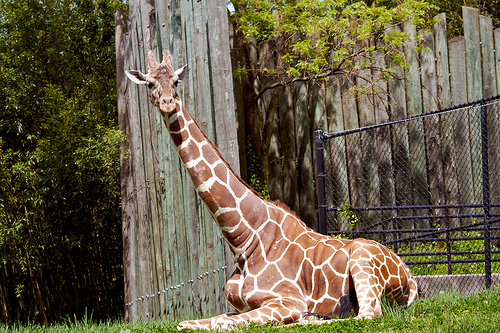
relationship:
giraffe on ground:
[120, 43, 433, 329] [4, 293, 499, 332]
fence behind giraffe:
[113, 4, 497, 317] [120, 43, 433, 329]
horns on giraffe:
[141, 49, 174, 68] [120, 43, 433, 329]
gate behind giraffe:
[305, 112, 499, 291] [120, 43, 433, 329]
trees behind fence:
[0, 1, 349, 286] [113, 4, 497, 317]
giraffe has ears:
[120, 43, 433, 329] [126, 65, 192, 83]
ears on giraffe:
[126, 65, 192, 83] [120, 43, 433, 329]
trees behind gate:
[0, 1, 349, 286] [305, 112, 499, 291]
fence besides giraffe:
[113, 4, 497, 317] [120, 43, 433, 329]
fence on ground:
[113, 4, 497, 317] [4, 293, 499, 332]